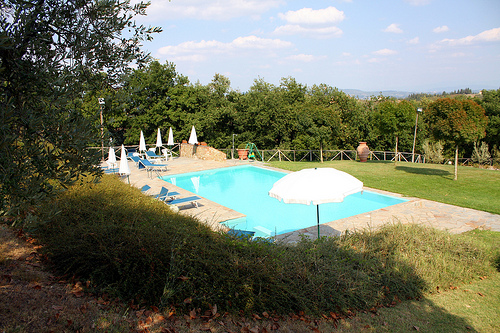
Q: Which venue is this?
A: This is a backyard.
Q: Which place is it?
A: It is a backyard.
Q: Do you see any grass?
A: Yes, there is grass.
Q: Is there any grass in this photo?
A: Yes, there is grass.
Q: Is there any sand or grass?
A: Yes, there is grass.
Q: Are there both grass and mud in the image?
A: No, there is grass but no mud.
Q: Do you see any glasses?
A: No, there are no glasses.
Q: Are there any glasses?
A: No, there are no glasses.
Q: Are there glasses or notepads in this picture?
A: No, there are no glasses or notepads.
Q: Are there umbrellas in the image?
A: Yes, there are umbrellas.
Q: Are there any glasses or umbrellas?
A: Yes, there are umbrellas.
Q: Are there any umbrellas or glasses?
A: Yes, there are umbrellas.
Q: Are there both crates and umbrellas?
A: No, there are umbrellas but no crates.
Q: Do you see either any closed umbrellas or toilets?
A: Yes, there are closed umbrellas.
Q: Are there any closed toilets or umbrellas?
A: Yes, there are closed umbrellas.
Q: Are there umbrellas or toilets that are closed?
A: Yes, the umbrellas are closed.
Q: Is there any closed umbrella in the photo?
A: Yes, there are closed umbrellas.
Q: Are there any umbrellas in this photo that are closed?
A: Yes, there are closed umbrellas.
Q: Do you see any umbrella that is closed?
A: Yes, there are umbrellas that are closed.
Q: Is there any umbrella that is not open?
A: Yes, there are closed umbrellas.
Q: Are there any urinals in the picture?
A: No, there are no urinals.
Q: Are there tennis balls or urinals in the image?
A: No, there are no urinals or tennis balls.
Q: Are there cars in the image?
A: No, there are no cars.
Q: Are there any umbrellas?
A: Yes, there are umbrellas.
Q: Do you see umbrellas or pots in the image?
A: Yes, there are umbrellas.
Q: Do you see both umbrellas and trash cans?
A: No, there are umbrellas but no trash cans.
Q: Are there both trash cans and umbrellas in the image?
A: No, there are umbrellas but no trash cans.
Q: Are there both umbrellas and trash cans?
A: No, there are umbrellas but no trash cans.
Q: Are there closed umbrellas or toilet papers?
A: Yes, there are closed umbrellas.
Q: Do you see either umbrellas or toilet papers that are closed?
A: Yes, the umbrellas are closed.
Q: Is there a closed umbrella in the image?
A: Yes, there are closed umbrellas.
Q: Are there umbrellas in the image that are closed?
A: Yes, there are umbrellas that are closed.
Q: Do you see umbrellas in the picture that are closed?
A: Yes, there are umbrellas that are closed.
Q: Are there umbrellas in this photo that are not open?
A: Yes, there are closed umbrellas.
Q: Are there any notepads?
A: No, there are no notepads.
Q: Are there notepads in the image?
A: No, there are no notepads.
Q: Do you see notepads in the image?
A: No, there are no notepads.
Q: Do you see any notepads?
A: No, there are no notepads.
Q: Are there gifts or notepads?
A: No, there are no notepads or gifts.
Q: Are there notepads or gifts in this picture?
A: No, there are no notepads or gifts.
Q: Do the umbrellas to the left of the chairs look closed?
A: Yes, the umbrellas are closed.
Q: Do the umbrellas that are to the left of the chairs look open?
A: No, the umbrellas are closed.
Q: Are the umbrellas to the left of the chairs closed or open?
A: The umbrellas are closed.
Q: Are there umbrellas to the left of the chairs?
A: Yes, there are umbrellas to the left of the chairs.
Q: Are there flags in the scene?
A: No, there are no flags.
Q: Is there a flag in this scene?
A: No, there are no flags.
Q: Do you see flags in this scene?
A: No, there are no flags.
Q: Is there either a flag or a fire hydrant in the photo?
A: No, there are no flags or fire hydrants.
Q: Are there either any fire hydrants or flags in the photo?
A: No, there are no flags or fire hydrants.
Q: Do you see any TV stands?
A: No, there are no TV stands.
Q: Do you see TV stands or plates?
A: No, there are no TV stands or plates.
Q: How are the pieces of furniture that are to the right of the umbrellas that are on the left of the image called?
A: The pieces of furniture are chairs.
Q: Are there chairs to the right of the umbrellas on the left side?
A: Yes, there are chairs to the right of the umbrellas.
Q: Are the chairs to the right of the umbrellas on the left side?
A: Yes, the chairs are to the right of the umbrellas.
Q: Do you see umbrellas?
A: Yes, there is an umbrella.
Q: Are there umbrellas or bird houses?
A: Yes, there is an umbrella.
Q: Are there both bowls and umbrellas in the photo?
A: No, there is an umbrella but no bowls.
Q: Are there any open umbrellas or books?
A: Yes, there is an open umbrella.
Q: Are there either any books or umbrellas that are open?
A: Yes, the umbrella is open.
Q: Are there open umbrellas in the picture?
A: Yes, there is an open umbrella.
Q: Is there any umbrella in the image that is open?
A: Yes, there is an umbrella that is open.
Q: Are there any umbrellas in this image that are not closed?
A: Yes, there is a open umbrella.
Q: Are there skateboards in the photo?
A: No, there are no skateboards.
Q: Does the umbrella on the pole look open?
A: Yes, the umbrella is open.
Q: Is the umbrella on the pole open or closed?
A: The umbrella is open.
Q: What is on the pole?
A: The umbrella is on the pole.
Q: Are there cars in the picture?
A: No, there are no cars.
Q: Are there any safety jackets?
A: No, there are no safety jackets.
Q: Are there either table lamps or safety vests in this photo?
A: No, there are no safety vests or table lamps.